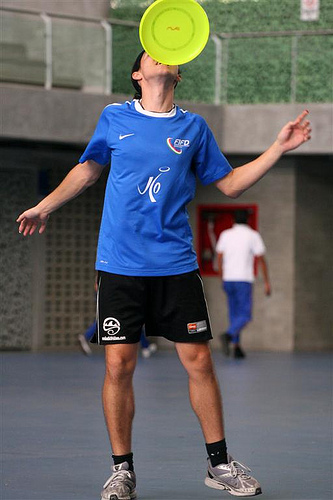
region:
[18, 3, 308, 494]
A man is biting on a frisbee.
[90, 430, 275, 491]
The man is wearing black socks.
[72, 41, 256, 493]
The man is wearing a uniform.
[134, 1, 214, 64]
A yellow frisbee.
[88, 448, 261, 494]
The man is wearing sneakers.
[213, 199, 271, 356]
A man in the background.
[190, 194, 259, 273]
The fire hose is in this case, behind the glass.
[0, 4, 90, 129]
Stands.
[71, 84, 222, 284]
The man is wearing a blue shirt.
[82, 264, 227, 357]
The man is wearing black shorts.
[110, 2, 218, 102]
mans head with a frisbee balanced on his chin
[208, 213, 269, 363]
man white shirt walking away in distance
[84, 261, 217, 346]
blue shorts with a white round symbol on one leg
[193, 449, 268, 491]
grey white tennis shoe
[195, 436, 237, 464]
black sock protruding from grey shoe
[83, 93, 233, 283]
blue shirt with the symbol FIFD on the left breast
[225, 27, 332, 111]
fence on top of a cement wall in the distance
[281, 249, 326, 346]
grey cement wall in the distance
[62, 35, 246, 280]
man in blue shirt with frisbee balanced on his chin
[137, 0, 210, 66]
a bright yellow frisbee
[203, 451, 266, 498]
one foot is off the ground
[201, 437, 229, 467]
one black sock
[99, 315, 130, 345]
a white logo on black shorts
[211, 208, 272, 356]
a man is walking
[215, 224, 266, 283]
a white short sleeved shirt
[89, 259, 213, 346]
black sports shorts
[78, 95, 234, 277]
a blue short sleeved shirt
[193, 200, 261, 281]
a red square on the wall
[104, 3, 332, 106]
a green hedge row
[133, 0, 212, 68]
person touching Frisbee with their face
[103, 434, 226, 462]
person wearing black socks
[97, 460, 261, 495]
person wearing grey sneakers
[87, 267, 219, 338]
person wearing black shorts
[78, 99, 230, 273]
person wearing blue shirt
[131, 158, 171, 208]
white design on person's shirt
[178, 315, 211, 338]
red, grey, black and white tag on person's shorts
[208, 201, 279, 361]
slightly blurry image of person walking in the background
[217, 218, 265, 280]
person wearing white shirt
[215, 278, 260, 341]
person wearing blue pants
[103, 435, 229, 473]
the boy is wearing black socks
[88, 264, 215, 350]
the boy is wearing black shorts with a white stripe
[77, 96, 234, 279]
the boy is wearing a blue shirt with a white collar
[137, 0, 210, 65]
the boy has a yellow frisbee in his mouth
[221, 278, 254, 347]
the man walking behind the boy is wearing blue jeans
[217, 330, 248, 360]
the man walking behind the boy is wearing black shoes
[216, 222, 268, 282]
the man walking behind the boy is wearing a white shirt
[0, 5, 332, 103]
the stone wall behind the boy has a chain link fence on top of it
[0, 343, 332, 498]
the floor beneath the boy is grey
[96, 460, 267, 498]
the boy is wearing grey tennis shoes